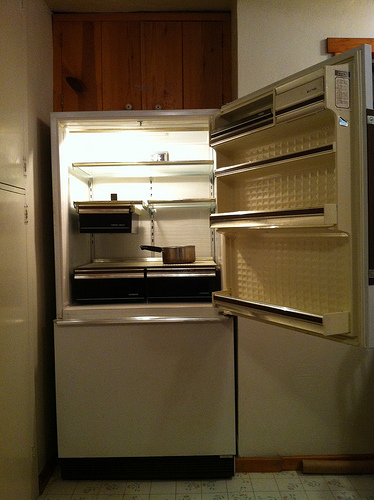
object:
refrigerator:
[59, 118, 217, 306]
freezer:
[51, 313, 236, 458]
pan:
[140, 242, 196, 263]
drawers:
[68, 198, 216, 206]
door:
[209, 61, 351, 336]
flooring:
[226, 482, 256, 494]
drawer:
[142, 269, 221, 302]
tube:
[292, 457, 364, 478]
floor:
[261, 469, 288, 496]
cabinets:
[52, 11, 231, 112]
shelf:
[88, 164, 206, 178]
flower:
[88, 484, 138, 496]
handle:
[52, 317, 224, 328]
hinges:
[208, 206, 323, 226]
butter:
[287, 89, 304, 104]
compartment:
[272, 75, 325, 123]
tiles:
[244, 473, 282, 496]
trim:
[15, 133, 43, 210]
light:
[84, 132, 144, 149]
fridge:
[53, 237, 220, 307]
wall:
[240, 8, 300, 56]